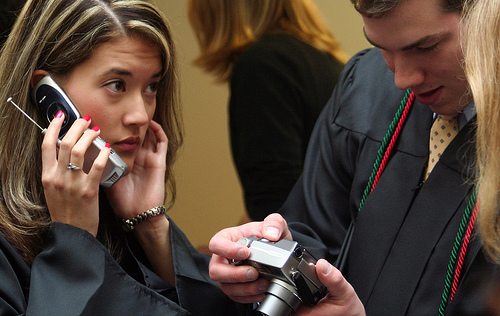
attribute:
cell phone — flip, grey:
[26, 75, 126, 187]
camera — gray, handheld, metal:
[237, 238, 328, 315]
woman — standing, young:
[3, 4, 219, 314]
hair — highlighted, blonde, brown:
[1, 2, 178, 244]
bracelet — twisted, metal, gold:
[120, 203, 171, 234]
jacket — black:
[1, 224, 240, 313]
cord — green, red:
[360, 93, 477, 315]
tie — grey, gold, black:
[425, 113, 458, 181]